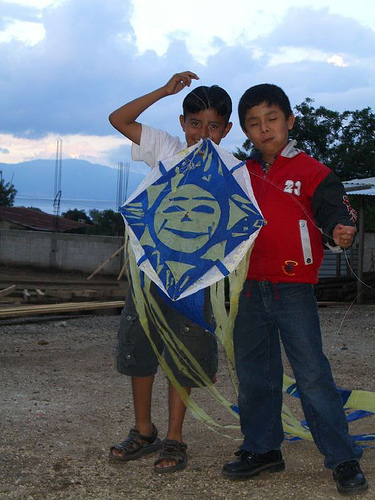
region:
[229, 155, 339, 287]
red jacket on boy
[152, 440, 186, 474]
black sandal on boy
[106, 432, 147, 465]
black sandal on boy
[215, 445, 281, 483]
black shoe on boy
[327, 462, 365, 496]
black shoe on boy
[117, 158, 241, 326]
kite in boys hand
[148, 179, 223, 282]
sun on the kite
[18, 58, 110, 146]
blue sky with clouds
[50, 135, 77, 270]
power line in background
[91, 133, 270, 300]
diamond shaped blue and yellow kite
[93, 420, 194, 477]
two boys feet wearing dark sandals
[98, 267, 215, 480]
boy wearing dark shorts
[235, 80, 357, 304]
boy wearing red jacket with dark sleeves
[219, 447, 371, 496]
boy wearing blue jeans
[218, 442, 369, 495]
boy wearing black shoes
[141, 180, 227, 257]
yellow painted face on blue background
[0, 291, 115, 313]
long light colored plank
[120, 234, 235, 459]
yellow plastic streaming from yellow and blue kite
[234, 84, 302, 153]
dark haired boy with eyes closed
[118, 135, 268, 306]
A kite with a sun on it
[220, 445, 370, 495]
Pair of black dress shoes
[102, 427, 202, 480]
A pair of black sandals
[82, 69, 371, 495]
Two young boys with a kite.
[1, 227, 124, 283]
A cement wall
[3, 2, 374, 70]
White fluffy clouds in the sky.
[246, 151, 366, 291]
Red and black jacket with the number 23 on it.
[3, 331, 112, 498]
A gravel road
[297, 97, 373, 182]
A tall tree with leaves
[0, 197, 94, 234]
Roof of a house.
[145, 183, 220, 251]
the image of a face on a kite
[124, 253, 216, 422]
yellow streamers from a kite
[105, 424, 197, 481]
brown sandals on a little boy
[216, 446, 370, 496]
black rugged boots on a little boy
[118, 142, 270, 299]
a blue and white kite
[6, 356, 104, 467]
brown and gray gravel on the ground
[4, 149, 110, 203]
a mountain behind power poles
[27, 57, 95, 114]
dark gray clouds in the sky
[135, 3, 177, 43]
the sun glowing from behind clouds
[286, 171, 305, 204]
the number 23 on a boy's shirt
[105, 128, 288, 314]
blue and yellow happy face kite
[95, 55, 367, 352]
two children playing with a kite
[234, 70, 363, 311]
young boy in red jacket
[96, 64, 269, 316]
young boy holding a kite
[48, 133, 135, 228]
electric lines in the background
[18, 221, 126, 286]
concrete wall fence wood propped on the wall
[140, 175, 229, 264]
yellow and blue happy face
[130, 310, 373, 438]
yellow and blue streamers of kite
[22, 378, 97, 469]
sand and gravel ground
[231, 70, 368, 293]
young boy making a funny face